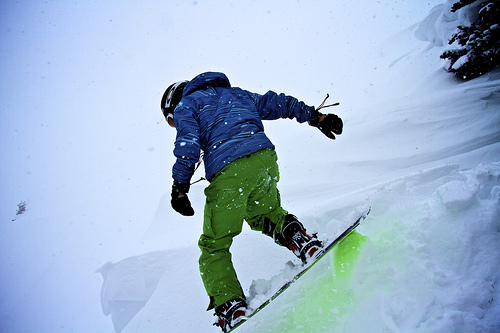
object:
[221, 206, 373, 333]
snowboard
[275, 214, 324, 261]
snow boot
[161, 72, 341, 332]
man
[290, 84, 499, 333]
snow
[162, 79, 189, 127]
helmet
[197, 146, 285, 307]
pants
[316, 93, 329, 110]
strings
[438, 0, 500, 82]
tree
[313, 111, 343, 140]
glove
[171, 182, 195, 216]
glove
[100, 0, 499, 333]
slope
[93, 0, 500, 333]
hill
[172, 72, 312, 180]
coat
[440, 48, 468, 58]
limbs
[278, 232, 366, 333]
reflection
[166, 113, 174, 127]
snow goggles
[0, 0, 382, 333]
sky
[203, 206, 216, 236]
pocket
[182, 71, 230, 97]
hood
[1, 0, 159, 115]
clouds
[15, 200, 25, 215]
bird